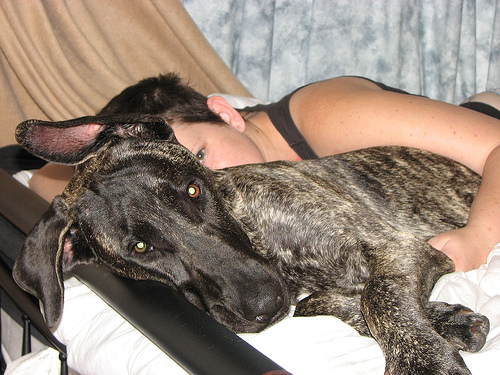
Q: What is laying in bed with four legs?
A: A dog.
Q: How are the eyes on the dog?
A: Open.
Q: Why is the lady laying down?
A: Resting.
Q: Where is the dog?
A: In bed.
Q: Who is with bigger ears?
A: Dog.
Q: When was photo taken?
A: Daytime.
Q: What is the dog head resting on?
A: Bed rail.